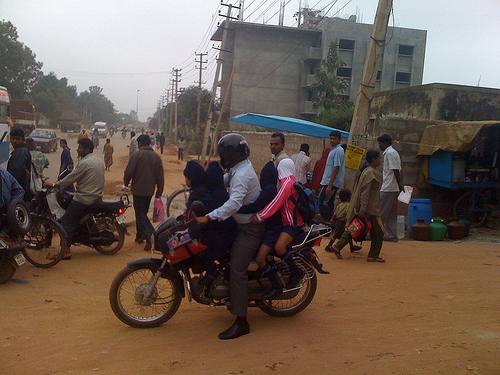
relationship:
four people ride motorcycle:
[159, 130, 311, 347] [106, 207, 331, 327]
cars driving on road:
[32, 120, 52, 140] [357, 261, 402, 326]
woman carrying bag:
[344, 146, 397, 266] [344, 219, 370, 243]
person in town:
[123, 134, 171, 246] [5, 2, 484, 364]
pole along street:
[169, 69, 184, 153] [0, 112, 201, 373]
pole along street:
[194, 53, 206, 148] [0, 112, 201, 373]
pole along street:
[205, 42, 220, 170] [0, 112, 201, 373]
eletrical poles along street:
[344, 0, 396, 191] [0, 112, 201, 373]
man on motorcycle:
[192, 133, 265, 341] [118, 191, 359, 351]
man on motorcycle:
[67, 141, 126, 192] [35, 183, 177, 263]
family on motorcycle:
[166, 133, 311, 245] [110, 213, 327, 324]